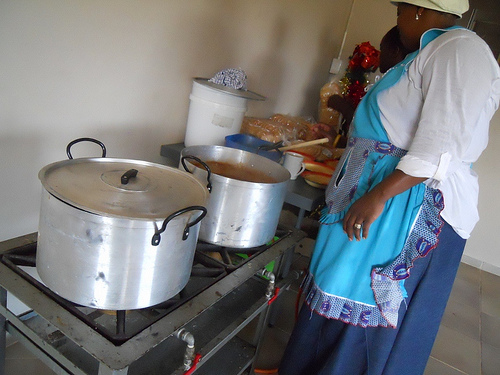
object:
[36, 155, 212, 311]
pot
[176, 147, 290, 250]
pot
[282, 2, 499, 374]
person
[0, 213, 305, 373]
stove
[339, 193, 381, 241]
hand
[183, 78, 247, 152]
bucket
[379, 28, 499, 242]
shirt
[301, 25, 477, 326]
apron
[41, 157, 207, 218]
lid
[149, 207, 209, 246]
handle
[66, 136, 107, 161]
handle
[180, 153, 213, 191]
handle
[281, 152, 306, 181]
cup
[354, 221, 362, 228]
ring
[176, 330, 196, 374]
line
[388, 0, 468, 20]
hat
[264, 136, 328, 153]
utensil